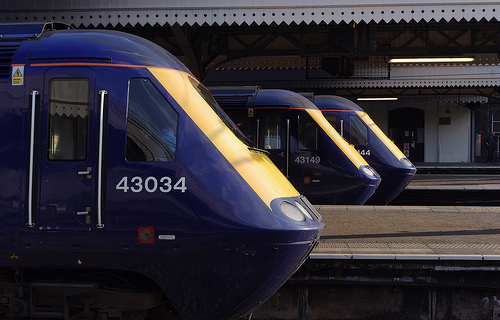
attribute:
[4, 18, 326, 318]
train — yellow, blue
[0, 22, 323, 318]
engine — blue, painted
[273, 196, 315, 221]
lights — round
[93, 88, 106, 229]
handle — Long , white 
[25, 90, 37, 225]
handle — Long , white 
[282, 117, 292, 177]
handle — Long , white 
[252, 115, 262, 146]
handle — Long , white 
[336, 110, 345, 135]
handle — Long , white 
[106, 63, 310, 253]
sticker — warning, yellow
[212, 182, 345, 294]
nose — pointed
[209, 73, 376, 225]
train — yellow, blue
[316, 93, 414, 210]
train — yellow, blue